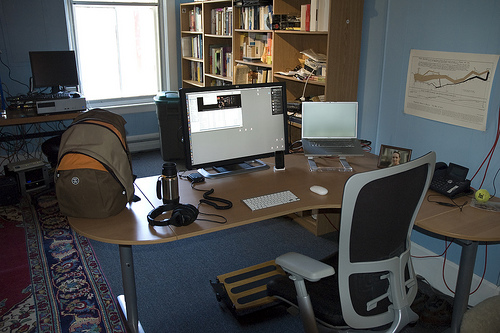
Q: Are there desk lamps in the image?
A: No, there are no desk lamps.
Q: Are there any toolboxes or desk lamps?
A: No, there are no desk lamps or toolboxes.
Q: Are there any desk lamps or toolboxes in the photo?
A: No, there are no desk lamps or toolboxes.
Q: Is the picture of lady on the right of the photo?
A: Yes, the picture is on the right of the image.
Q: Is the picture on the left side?
A: No, the picture is on the right of the image.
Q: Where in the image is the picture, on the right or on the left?
A: The picture is on the right of the image.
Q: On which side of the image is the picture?
A: The picture is on the right of the image.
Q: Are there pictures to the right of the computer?
A: Yes, there is a picture to the right of the computer.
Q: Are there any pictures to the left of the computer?
A: No, the picture is to the right of the computer.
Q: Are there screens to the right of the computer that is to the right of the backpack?
A: No, there is a picture to the right of the computer.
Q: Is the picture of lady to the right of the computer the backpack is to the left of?
A: Yes, the picture is to the right of the computer.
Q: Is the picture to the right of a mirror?
A: No, the picture is to the right of the computer.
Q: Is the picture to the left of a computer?
A: No, the picture is to the right of a computer.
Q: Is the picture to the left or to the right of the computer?
A: The picture is to the right of the computer.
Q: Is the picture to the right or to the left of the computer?
A: The picture is to the right of the computer.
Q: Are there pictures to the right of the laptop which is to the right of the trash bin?
A: Yes, there is a picture to the right of the laptop.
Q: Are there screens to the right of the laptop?
A: No, there is a picture to the right of the laptop.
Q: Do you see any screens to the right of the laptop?
A: No, there is a picture to the right of the laptop.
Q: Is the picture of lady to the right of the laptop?
A: Yes, the picture is to the right of the laptop.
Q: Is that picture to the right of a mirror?
A: No, the picture is to the right of the laptop.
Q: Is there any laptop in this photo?
A: Yes, there is a laptop.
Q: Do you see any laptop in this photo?
A: Yes, there is a laptop.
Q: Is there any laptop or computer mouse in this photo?
A: Yes, there is a laptop.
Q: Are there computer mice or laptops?
A: Yes, there is a laptop.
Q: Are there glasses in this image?
A: No, there are no glasses.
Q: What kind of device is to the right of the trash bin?
A: The device is a laptop.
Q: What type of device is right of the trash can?
A: The device is a laptop.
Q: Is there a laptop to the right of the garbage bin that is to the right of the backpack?
A: Yes, there is a laptop to the right of the trash can.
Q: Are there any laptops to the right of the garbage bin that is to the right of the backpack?
A: Yes, there is a laptop to the right of the trash can.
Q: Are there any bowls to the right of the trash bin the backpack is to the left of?
A: No, there is a laptop to the right of the garbage bin.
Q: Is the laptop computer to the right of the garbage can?
A: Yes, the laptop computer is to the right of the garbage can.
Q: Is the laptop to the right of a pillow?
A: No, the laptop is to the right of the garbage can.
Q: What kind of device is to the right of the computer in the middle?
A: The device is a laptop.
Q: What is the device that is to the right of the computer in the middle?
A: The device is a laptop.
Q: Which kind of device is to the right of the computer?
A: The device is a laptop.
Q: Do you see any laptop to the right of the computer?
A: Yes, there is a laptop to the right of the computer.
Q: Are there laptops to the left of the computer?
A: No, the laptop is to the right of the computer.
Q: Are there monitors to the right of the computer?
A: No, there is a laptop to the right of the computer.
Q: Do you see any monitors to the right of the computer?
A: No, there is a laptop to the right of the computer.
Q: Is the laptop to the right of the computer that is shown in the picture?
A: Yes, the laptop is to the right of the computer.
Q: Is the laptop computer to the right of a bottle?
A: No, the laptop computer is to the right of the computer.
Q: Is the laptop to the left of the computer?
A: No, the laptop is to the right of the computer.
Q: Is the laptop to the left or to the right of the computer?
A: The laptop is to the right of the computer.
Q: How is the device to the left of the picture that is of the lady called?
A: The device is a laptop.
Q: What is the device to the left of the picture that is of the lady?
A: The device is a laptop.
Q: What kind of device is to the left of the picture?
A: The device is a laptop.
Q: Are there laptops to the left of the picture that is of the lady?
A: Yes, there is a laptop to the left of the picture.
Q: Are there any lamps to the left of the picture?
A: No, there is a laptop to the left of the picture.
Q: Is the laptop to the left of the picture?
A: Yes, the laptop is to the left of the picture.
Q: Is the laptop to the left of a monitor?
A: No, the laptop is to the left of the picture.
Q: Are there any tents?
A: No, there are no tents.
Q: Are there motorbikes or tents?
A: No, there are no tents or motorbikes.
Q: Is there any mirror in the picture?
A: No, there are no mirrors.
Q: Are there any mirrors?
A: No, there are no mirrors.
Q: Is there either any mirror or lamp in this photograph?
A: No, there are no mirrors or lamps.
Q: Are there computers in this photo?
A: Yes, there is a computer.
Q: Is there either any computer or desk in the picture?
A: Yes, there is a computer.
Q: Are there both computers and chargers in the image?
A: No, there is a computer but no chargers.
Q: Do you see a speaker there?
A: No, there are no speakers.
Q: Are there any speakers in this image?
A: No, there are no speakers.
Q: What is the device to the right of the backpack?
A: The device is a computer.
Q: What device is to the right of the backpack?
A: The device is a computer.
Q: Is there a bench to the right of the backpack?
A: No, there is a computer to the right of the backpack.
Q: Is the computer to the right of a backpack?
A: Yes, the computer is to the right of a backpack.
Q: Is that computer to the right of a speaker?
A: No, the computer is to the right of a backpack.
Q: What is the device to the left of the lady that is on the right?
A: The device is a computer.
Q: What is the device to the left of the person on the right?
A: The device is a computer.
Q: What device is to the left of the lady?
A: The device is a computer.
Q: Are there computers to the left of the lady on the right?
A: Yes, there is a computer to the left of the lady.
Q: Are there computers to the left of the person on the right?
A: Yes, there is a computer to the left of the lady.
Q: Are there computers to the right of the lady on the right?
A: No, the computer is to the left of the lady.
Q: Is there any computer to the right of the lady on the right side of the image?
A: No, the computer is to the left of the lady.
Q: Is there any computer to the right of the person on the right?
A: No, the computer is to the left of the lady.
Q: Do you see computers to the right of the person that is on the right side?
A: No, the computer is to the left of the lady.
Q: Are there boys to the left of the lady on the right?
A: No, there is a computer to the left of the lady.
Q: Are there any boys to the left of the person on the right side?
A: No, there is a computer to the left of the lady.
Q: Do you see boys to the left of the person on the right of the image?
A: No, there is a computer to the left of the lady.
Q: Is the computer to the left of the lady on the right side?
A: Yes, the computer is to the left of the lady.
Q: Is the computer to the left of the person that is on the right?
A: Yes, the computer is to the left of the lady.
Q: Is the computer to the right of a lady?
A: No, the computer is to the left of a lady.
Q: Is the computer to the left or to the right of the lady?
A: The computer is to the left of the lady.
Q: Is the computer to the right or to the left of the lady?
A: The computer is to the left of the lady.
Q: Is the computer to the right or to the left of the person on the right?
A: The computer is to the left of the lady.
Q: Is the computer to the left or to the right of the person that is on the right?
A: The computer is to the left of the lady.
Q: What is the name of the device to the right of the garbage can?
A: The device is a computer.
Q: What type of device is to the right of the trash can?
A: The device is a computer.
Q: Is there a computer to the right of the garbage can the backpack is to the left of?
A: Yes, there is a computer to the right of the trash bin.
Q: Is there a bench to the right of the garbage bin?
A: No, there is a computer to the right of the garbage bin.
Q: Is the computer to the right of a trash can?
A: Yes, the computer is to the right of a trash can.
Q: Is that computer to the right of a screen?
A: No, the computer is to the right of a trash can.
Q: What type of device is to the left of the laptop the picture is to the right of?
A: The device is a computer.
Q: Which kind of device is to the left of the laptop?
A: The device is a computer.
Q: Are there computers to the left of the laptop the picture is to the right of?
A: Yes, there is a computer to the left of the laptop.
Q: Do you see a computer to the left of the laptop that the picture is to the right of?
A: Yes, there is a computer to the left of the laptop.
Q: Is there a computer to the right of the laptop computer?
A: No, the computer is to the left of the laptop computer.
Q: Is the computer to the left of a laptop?
A: Yes, the computer is to the left of a laptop.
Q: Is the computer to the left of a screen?
A: No, the computer is to the left of a laptop.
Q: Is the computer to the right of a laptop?
A: No, the computer is to the left of a laptop.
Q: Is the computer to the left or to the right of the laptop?
A: The computer is to the left of the laptop.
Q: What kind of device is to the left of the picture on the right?
A: The device is a computer.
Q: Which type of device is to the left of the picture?
A: The device is a computer.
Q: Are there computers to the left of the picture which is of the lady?
A: Yes, there is a computer to the left of the picture.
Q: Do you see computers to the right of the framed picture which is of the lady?
A: No, the computer is to the left of the picture.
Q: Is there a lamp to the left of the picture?
A: No, there is a computer to the left of the picture.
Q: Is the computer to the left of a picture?
A: Yes, the computer is to the left of a picture.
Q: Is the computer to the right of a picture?
A: No, the computer is to the left of a picture.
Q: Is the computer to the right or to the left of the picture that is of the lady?
A: The computer is to the left of the picture.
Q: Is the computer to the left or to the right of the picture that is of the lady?
A: The computer is to the left of the picture.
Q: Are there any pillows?
A: No, there are no pillows.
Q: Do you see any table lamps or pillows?
A: No, there are no pillows or table lamps.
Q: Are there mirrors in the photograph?
A: No, there are no mirrors.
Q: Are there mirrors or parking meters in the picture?
A: No, there are no mirrors or parking meters.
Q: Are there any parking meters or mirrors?
A: No, there are no mirrors or parking meters.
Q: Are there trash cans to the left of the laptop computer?
A: Yes, there is a trash can to the left of the laptop computer.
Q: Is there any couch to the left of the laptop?
A: No, there is a trash can to the left of the laptop.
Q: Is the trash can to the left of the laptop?
A: Yes, the trash can is to the left of the laptop.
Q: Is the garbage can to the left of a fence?
A: No, the garbage can is to the left of the laptop.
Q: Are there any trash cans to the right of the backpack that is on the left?
A: Yes, there is a trash can to the right of the backpack.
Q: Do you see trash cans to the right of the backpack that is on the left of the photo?
A: Yes, there is a trash can to the right of the backpack.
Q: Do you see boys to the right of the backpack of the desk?
A: No, there is a trash can to the right of the backpack.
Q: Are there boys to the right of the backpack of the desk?
A: No, there is a trash can to the right of the backpack.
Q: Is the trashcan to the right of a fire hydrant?
A: No, the trashcan is to the right of the backpack.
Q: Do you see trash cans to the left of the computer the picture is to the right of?
A: Yes, there is a trash can to the left of the computer.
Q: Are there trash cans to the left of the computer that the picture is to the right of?
A: Yes, there is a trash can to the left of the computer.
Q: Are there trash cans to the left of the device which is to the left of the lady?
A: Yes, there is a trash can to the left of the computer.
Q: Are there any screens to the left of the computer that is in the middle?
A: No, there is a trash can to the left of the computer.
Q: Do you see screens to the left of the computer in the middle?
A: No, there is a trash can to the left of the computer.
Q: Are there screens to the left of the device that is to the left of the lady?
A: No, there is a trash can to the left of the computer.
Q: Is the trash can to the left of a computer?
A: Yes, the trash can is to the left of a computer.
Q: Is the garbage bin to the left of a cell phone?
A: No, the garbage bin is to the left of a computer.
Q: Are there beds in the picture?
A: No, there are no beds.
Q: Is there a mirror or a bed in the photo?
A: No, there are no beds or mirrors.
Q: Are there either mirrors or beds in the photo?
A: No, there are no beds or mirrors.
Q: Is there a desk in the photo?
A: Yes, there is a desk.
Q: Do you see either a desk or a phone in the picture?
A: Yes, there is a desk.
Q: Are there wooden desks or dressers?
A: Yes, there is a wood desk.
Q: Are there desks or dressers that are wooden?
A: Yes, the desk is wooden.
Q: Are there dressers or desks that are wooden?
A: Yes, the desk is wooden.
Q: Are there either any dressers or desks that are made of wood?
A: Yes, the desk is made of wood.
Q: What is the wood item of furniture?
A: The piece of furniture is a desk.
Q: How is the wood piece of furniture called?
A: The piece of furniture is a desk.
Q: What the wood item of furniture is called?
A: The piece of furniture is a desk.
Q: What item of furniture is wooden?
A: The piece of furniture is a desk.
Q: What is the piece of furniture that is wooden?
A: The piece of furniture is a desk.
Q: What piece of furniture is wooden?
A: The piece of furniture is a desk.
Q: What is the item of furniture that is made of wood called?
A: The piece of furniture is a desk.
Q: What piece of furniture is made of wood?
A: The piece of furniture is a desk.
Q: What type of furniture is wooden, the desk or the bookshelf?
A: The desk is wooden.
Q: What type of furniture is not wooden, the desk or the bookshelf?
A: The bookshelf is not wooden.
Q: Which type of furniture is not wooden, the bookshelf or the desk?
A: The bookshelf is not wooden.